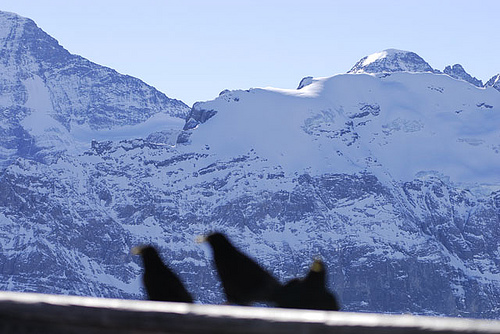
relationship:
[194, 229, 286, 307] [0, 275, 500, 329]
animal in field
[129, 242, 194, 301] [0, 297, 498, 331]
animal in field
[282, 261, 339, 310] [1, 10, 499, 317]
animal in field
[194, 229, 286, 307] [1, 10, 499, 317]
animal in field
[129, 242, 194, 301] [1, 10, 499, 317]
animal in field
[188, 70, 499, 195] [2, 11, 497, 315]
snow on mountain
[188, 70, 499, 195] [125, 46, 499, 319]
snow on mountain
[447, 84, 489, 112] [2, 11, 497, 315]
snow on mountain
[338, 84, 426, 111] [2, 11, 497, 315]
snow on mountain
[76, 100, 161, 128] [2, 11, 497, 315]
snow on mountain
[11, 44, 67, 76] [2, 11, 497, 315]
snow on mountain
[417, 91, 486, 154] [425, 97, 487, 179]
view of snow